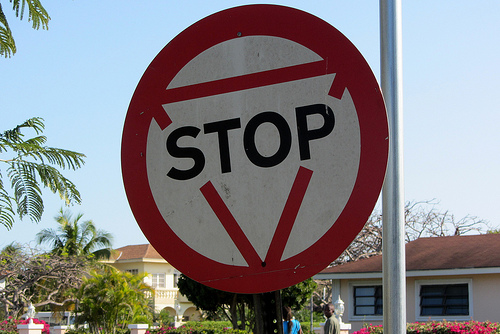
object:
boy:
[322, 303, 339, 334]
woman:
[275, 304, 304, 331]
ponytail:
[282, 306, 293, 334]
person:
[283, 306, 303, 333]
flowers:
[447, 321, 498, 332]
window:
[419, 283, 470, 316]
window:
[150, 271, 165, 288]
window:
[348, 280, 383, 322]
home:
[307, 233, 500, 333]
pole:
[380, 0, 407, 334]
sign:
[165, 103, 335, 181]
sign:
[120, 4, 389, 294]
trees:
[0, 256, 94, 333]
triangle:
[147, 53, 347, 272]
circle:
[120, 4, 389, 294]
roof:
[317, 233, 499, 274]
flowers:
[13, 317, 50, 333]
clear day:
[0, 0, 499, 334]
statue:
[25, 302, 36, 321]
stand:
[17, 324, 42, 332]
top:
[323, 318, 339, 334]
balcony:
[144, 287, 185, 298]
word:
[164, 101, 336, 181]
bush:
[352, 317, 500, 334]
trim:
[415, 277, 474, 321]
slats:
[419, 284, 468, 315]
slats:
[353, 285, 382, 316]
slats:
[152, 273, 166, 288]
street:
[0, 245, 496, 334]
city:
[0, 234, 499, 333]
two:
[282, 304, 340, 334]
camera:
[254, 216, 438, 334]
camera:
[4, 66, 484, 334]